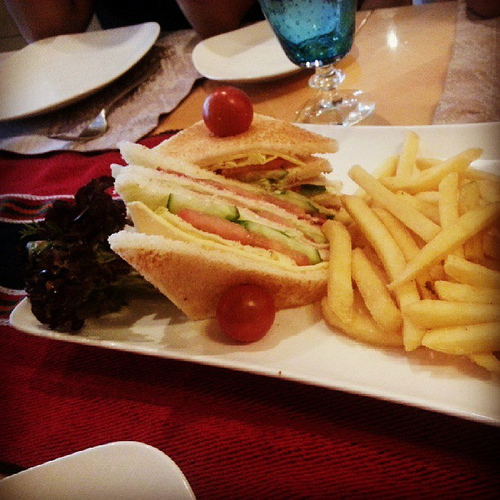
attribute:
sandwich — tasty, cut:
[110, 84, 339, 346]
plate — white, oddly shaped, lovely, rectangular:
[7, 119, 499, 427]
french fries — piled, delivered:
[319, 129, 499, 375]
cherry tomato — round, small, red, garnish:
[203, 84, 254, 138]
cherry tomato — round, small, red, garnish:
[218, 281, 276, 345]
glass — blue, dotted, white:
[261, 0, 375, 127]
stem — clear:
[308, 62, 346, 104]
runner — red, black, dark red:
[1, 128, 498, 496]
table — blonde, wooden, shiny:
[148, 0, 459, 129]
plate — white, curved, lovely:
[1, 439, 201, 500]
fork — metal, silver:
[46, 61, 161, 142]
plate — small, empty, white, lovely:
[192, 16, 312, 83]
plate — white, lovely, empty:
[1, 21, 160, 126]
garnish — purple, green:
[21, 174, 161, 334]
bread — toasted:
[105, 228, 328, 320]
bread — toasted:
[148, 106, 339, 161]